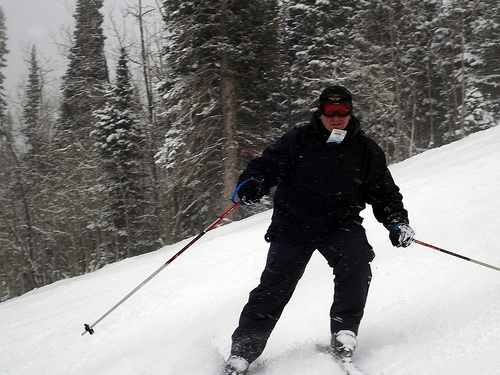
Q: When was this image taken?
A: Winter.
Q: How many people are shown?
A: One.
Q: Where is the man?
A: Ski slope.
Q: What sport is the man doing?
A: Skiing.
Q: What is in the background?
A: Trees.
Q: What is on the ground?
A: Snow.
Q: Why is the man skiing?
A: Exercise.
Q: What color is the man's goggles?
A: Orange.